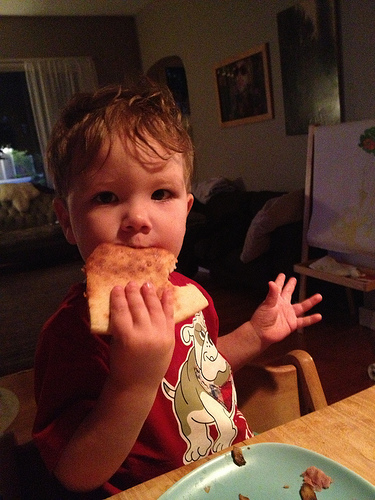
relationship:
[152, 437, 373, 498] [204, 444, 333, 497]
plate with meat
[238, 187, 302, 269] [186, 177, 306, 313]
pillow on couch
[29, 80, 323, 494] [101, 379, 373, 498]
boy at a dining table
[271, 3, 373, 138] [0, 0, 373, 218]
painting on wall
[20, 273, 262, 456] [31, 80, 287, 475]
red shirt on little boy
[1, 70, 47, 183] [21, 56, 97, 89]
window with curtains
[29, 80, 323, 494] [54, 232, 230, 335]
boy eats pizza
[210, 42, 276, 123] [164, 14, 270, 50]
picture hanging on wall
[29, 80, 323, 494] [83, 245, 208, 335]
boy holding food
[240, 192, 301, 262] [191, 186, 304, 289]
pillow on couch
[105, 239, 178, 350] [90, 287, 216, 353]
slice of pizza being held upside down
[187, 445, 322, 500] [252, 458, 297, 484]
food crumbs on plate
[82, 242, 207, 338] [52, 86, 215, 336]
toasted bread slice boy eating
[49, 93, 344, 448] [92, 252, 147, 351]
boy eating a slice of pizza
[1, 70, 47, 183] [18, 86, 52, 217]
window showing that its night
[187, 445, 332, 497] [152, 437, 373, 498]
food on plate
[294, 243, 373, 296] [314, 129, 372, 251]
table for art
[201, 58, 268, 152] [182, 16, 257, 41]
framed art on wall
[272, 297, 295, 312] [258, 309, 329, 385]
hand open hand open